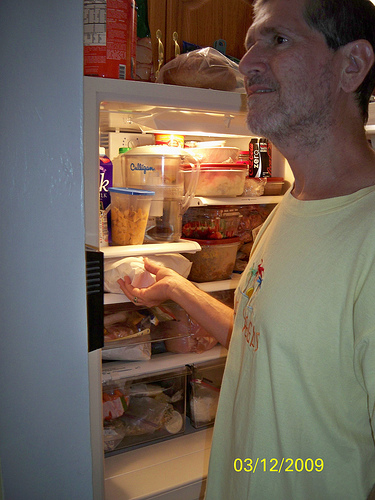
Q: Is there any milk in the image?
A: Yes, there is milk.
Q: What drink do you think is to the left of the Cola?
A: The drink is milk.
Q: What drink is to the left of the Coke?
A: The drink is milk.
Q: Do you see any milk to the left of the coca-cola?
A: Yes, there is milk to the left of the coca-cola.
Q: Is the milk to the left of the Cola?
A: Yes, the milk is to the left of the Cola.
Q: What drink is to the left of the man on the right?
A: The drink is milk.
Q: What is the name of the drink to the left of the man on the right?
A: The drink is milk.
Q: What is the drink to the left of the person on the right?
A: The drink is milk.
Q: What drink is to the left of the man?
A: The drink is milk.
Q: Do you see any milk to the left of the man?
A: Yes, there is milk to the left of the man.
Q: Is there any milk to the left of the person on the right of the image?
A: Yes, there is milk to the left of the man.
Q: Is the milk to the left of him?
A: Yes, the milk is to the left of a man.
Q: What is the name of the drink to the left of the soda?
A: The drink is milk.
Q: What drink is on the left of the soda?
A: The drink is milk.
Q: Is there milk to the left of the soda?
A: Yes, there is milk to the left of the soda.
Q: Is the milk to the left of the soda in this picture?
A: Yes, the milk is to the left of the soda.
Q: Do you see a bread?
A: Yes, there is a bread.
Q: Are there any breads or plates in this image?
A: Yes, there is a bread.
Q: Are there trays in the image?
A: No, there are no trays.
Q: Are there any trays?
A: No, there are no trays.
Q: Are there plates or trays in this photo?
A: No, there are no trays or plates.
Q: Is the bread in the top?
A: Yes, the bread is in the top of the image.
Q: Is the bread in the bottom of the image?
A: No, the bread is in the top of the image.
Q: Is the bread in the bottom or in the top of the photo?
A: The bread is in the top of the image.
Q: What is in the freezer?
A: The bread is in the freezer.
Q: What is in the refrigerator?
A: The bread is in the freezer.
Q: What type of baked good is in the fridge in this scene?
A: The food is a bread.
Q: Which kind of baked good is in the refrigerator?
A: The food is a bread.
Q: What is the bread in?
A: The bread is in the refrigerator.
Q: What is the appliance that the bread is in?
A: The appliance is a refrigerator.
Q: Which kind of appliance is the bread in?
A: The bread is in the freezer.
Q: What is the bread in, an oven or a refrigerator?
A: The bread is in a refrigerator.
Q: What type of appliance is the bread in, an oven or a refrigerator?
A: The bread is in a refrigerator.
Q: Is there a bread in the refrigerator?
A: Yes, there is a bread in the refrigerator.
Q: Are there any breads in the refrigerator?
A: Yes, there is a bread in the refrigerator.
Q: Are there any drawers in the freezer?
A: No, there is a bread in the freezer.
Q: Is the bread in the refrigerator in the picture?
A: Yes, the bread is in the refrigerator.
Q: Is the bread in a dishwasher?
A: No, the bread is in the refrigerator.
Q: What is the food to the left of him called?
A: The food is a bread.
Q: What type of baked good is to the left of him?
A: The food is a bread.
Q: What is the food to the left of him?
A: The food is a bread.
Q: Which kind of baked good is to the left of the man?
A: The food is a bread.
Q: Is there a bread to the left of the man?
A: Yes, there is a bread to the left of the man.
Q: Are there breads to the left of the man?
A: Yes, there is a bread to the left of the man.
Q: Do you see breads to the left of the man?
A: Yes, there is a bread to the left of the man.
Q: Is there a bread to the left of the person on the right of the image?
A: Yes, there is a bread to the left of the man.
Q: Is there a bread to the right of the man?
A: No, the bread is to the left of the man.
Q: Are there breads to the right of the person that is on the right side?
A: No, the bread is to the left of the man.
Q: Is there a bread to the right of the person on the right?
A: No, the bread is to the left of the man.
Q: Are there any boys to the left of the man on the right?
A: No, there is a bread to the left of the man.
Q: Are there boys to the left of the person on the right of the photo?
A: No, there is a bread to the left of the man.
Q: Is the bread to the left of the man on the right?
A: Yes, the bread is to the left of the man.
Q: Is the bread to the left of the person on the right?
A: Yes, the bread is to the left of the man.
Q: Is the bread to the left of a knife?
A: No, the bread is to the left of the man.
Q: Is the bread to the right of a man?
A: No, the bread is to the left of a man.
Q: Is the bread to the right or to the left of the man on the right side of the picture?
A: The bread is to the left of the man.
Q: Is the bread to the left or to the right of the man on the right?
A: The bread is to the left of the man.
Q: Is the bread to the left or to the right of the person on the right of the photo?
A: The bread is to the left of the man.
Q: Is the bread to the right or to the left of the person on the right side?
A: The bread is to the left of the man.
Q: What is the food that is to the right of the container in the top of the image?
A: The food is a bread.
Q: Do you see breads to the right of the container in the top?
A: Yes, there is a bread to the right of the container.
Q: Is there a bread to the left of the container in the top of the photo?
A: No, the bread is to the right of the container.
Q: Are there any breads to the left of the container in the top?
A: No, the bread is to the right of the container.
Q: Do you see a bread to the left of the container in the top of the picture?
A: No, the bread is to the right of the container.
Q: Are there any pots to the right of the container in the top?
A: No, there is a bread to the right of the container.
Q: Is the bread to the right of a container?
A: Yes, the bread is to the right of a container.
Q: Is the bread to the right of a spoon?
A: No, the bread is to the right of a container.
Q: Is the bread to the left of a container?
A: No, the bread is to the right of a container.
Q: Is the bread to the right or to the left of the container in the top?
A: The bread is to the right of the container.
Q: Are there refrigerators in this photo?
A: Yes, there is a refrigerator.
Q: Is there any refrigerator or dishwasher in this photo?
A: Yes, there is a refrigerator.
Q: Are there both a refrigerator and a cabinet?
A: Yes, there are both a refrigerator and a cabinet.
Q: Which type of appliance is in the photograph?
A: The appliance is a refrigerator.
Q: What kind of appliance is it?
A: The appliance is a refrigerator.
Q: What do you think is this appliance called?
A: This is a refrigerator.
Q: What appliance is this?
A: This is a refrigerator.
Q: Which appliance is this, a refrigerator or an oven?
A: This is a refrigerator.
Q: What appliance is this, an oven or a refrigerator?
A: This is a refrigerator.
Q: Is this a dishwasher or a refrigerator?
A: This is a refrigerator.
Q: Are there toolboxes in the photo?
A: No, there are no toolboxes.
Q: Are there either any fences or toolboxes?
A: No, there are no toolboxes or fences.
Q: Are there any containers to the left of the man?
A: Yes, there is a container to the left of the man.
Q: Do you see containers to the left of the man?
A: Yes, there is a container to the left of the man.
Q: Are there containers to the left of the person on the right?
A: Yes, there is a container to the left of the man.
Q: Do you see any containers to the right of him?
A: No, the container is to the left of the man.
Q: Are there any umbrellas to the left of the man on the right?
A: No, there is a container to the left of the man.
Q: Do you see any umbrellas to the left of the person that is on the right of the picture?
A: No, there is a container to the left of the man.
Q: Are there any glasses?
A: No, there are no glasses.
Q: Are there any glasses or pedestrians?
A: No, there are no glasses or pedestrians.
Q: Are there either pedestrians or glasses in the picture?
A: No, there are no glasses or pedestrians.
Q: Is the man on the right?
A: Yes, the man is on the right of the image.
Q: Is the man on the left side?
A: No, the man is on the right of the image.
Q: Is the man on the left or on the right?
A: The man is on the right of the image.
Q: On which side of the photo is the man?
A: The man is on the right of the image.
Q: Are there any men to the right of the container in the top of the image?
A: Yes, there is a man to the right of the container.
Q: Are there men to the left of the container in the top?
A: No, the man is to the right of the container.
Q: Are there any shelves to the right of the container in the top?
A: No, there is a man to the right of the container.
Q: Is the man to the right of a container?
A: Yes, the man is to the right of a container.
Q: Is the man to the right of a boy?
A: No, the man is to the right of a container.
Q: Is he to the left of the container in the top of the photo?
A: No, the man is to the right of the container.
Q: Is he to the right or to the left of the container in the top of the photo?
A: The man is to the right of the container.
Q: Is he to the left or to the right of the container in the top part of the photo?
A: The man is to the right of the container.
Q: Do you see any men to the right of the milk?
A: Yes, there is a man to the right of the milk.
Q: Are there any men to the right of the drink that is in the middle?
A: Yes, there is a man to the right of the milk.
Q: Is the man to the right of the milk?
A: Yes, the man is to the right of the milk.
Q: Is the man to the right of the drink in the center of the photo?
A: Yes, the man is to the right of the milk.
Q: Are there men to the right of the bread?
A: Yes, there is a man to the right of the bread.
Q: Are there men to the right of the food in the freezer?
A: Yes, there is a man to the right of the bread.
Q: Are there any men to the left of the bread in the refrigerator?
A: No, the man is to the right of the bread.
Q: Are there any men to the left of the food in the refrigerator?
A: No, the man is to the right of the bread.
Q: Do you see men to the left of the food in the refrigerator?
A: No, the man is to the right of the bread.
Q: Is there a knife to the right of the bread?
A: No, there is a man to the right of the bread.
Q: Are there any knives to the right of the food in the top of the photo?
A: No, there is a man to the right of the bread.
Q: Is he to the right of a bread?
A: Yes, the man is to the right of a bread.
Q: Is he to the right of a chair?
A: No, the man is to the right of a bread.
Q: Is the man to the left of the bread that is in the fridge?
A: No, the man is to the right of the bread.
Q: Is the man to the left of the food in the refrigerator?
A: No, the man is to the right of the bread.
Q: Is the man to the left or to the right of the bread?
A: The man is to the right of the bread.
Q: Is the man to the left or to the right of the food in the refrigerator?
A: The man is to the right of the bread.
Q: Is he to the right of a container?
A: Yes, the man is to the right of a container.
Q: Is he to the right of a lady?
A: No, the man is to the right of a container.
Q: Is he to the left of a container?
A: No, the man is to the right of a container.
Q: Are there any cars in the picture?
A: No, there are no cars.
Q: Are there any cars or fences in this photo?
A: No, there are no cars or fences.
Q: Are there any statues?
A: No, there are no statues.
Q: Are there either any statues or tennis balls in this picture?
A: No, there are no statues or tennis balls.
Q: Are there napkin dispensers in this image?
A: No, there are no napkin dispensers.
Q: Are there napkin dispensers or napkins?
A: No, there are no napkin dispensers or napkins.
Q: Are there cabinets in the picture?
A: Yes, there is a cabinet.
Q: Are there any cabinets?
A: Yes, there is a cabinet.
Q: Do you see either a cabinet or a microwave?
A: Yes, there is a cabinet.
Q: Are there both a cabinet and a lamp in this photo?
A: No, there is a cabinet but no lamps.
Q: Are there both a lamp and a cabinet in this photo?
A: No, there is a cabinet but no lamps.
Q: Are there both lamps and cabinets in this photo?
A: No, there is a cabinet but no lamps.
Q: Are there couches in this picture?
A: No, there are no couches.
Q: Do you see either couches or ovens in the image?
A: No, there are no couches or ovens.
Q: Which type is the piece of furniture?
A: The piece of furniture is a cabinet.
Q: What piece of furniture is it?
A: The piece of furniture is a cabinet.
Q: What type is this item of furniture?
A: This is a cabinet.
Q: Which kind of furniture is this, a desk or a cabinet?
A: This is a cabinet.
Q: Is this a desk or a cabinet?
A: This is a cabinet.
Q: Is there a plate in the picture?
A: No, there are no plates.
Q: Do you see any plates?
A: No, there are no plates.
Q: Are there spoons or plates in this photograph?
A: No, there are no plates or spoons.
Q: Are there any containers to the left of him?
A: Yes, there is a container to the left of the man.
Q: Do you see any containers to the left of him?
A: Yes, there is a container to the left of the man.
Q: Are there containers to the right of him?
A: No, the container is to the left of the man.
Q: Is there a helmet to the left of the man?
A: No, there is a container to the left of the man.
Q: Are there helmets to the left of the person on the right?
A: No, there is a container to the left of the man.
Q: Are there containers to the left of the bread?
A: Yes, there is a container to the left of the bread.